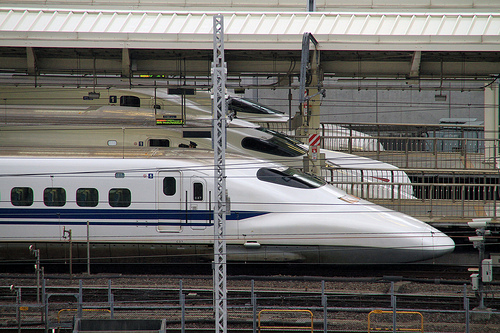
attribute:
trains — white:
[2, 147, 461, 274]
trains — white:
[0, 119, 425, 199]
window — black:
[107, 185, 132, 214]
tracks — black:
[0, 225, 497, 282]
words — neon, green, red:
[155, 115, 182, 127]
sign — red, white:
[307, 128, 323, 149]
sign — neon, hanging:
[154, 119, 188, 129]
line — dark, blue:
[2, 205, 254, 226]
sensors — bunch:
[477, 260, 492, 284]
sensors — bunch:
[467, 265, 479, 294]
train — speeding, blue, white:
[0, 152, 462, 279]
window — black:
[106, 185, 133, 209]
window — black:
[73, 187, 100, 207]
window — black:
[41, 185, 68, 206]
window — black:
[8, 185, 35, 206]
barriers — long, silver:
[316, 153, 498, 219]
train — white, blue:
[1, 143, 453, 263]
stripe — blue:
[1, 203, 271, 229]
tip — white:
[387, 214, 453, 259]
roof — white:
[0, 3, 497, 63]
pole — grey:
[204, 10, 236, 305]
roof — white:
[1, 6, 498, 51]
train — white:
[2, 85, 387, 154]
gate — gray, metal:
[328, 178, 485, 226]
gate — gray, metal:
[293, 164, 484, 200]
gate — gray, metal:
[284, 132, 484, 170]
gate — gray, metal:
[285, 132, 485, 154]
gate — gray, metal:
[248, 118, 484, 150]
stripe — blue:
[0, 206, 269, 221]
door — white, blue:
[155, 169, 185, 233]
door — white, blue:
[189, 176, 209, 229]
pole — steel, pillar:
[197, 39, 239, 330]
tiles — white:
[1, 0, 498, 52]